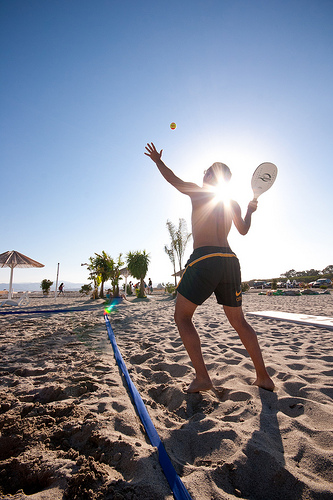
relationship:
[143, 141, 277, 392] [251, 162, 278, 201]
guy holding paddle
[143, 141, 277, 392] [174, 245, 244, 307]
guy wearing shorts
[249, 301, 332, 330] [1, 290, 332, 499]
board on sand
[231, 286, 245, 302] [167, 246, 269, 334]
nike logo on back of shorts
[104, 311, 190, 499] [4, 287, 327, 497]
blue line on ground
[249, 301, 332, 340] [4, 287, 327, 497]
board on ground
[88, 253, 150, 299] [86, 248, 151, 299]
umbrella behind trees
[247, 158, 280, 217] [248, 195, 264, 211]
paddle in hand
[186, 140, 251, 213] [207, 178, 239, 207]
sun showing glare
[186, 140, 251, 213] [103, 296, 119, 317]
sun reflecting a prism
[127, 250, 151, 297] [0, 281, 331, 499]
palms planted on beach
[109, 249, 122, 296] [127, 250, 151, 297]
tree planted on palms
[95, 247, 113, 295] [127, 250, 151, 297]
tree planted on palms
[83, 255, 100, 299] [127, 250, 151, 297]
tree planted on palms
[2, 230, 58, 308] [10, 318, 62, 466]
umbrella mounted on beach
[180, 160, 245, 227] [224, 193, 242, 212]
sun rays shinning over shoulder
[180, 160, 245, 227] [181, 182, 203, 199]
sun rays shinning over shoulder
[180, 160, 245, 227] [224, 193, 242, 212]
sun rays streaming over shoulder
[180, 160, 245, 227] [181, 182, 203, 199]
sun rays streaming over shoulder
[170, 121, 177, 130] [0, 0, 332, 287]
ball flying in sky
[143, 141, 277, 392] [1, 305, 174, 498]
guy standing in sand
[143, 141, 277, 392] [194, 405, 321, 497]
guy standing on in beach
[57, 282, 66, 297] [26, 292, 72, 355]
people standing on beach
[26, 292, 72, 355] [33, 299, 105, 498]
beach standing on sand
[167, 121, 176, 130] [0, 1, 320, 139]
ball flying in sky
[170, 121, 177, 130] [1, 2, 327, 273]
ball flying in air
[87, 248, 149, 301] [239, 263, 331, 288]
palms swaying in trees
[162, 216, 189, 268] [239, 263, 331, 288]
palms swaying in trees